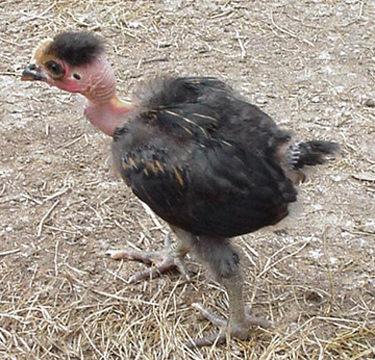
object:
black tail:
[285, 136, 340, 167]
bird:
[18, 27, 347, 351]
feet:
[187, 302, 272, 350]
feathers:
[121, 73, 334, 234]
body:
[111, 69, 294, 239]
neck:
[84, 85, 135, 136]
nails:
[128, 273, 135, 285]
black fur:
[113, 74, 290, 240]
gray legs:
[158, 223, 201, 261]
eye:
[42, 60, 66, 80]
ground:
[0, 0, 375, 360]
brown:
[30, 127, 97, 280]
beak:
[19, 63, 45, 81]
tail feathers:
[289, 133, 344, 176]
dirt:
[2, 134, 50, 217]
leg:
[190, 233, 251, 330]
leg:
[162, 213, 194, 262]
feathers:
[43, 28, 110, 68]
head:
[19, 27, 119, 99]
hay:
[3, 3, 373, 359]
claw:
[108, 235, 188, 284]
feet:
[109, 237, 192, 292]